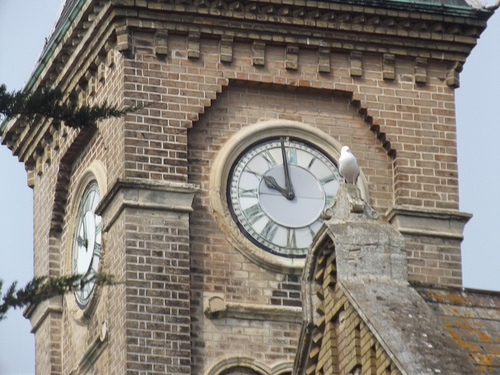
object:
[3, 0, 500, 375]
tower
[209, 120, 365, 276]
clock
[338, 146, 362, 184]
dove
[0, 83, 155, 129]
branch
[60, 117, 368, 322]
2 clocks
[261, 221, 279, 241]
numbers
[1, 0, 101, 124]
border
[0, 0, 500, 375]
sky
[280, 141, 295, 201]
hands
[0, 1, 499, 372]
scene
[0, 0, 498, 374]
building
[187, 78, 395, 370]
wall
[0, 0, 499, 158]
roof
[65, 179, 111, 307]
clock face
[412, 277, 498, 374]
roof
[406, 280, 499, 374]
old church roof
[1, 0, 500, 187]
top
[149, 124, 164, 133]
brick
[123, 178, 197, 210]
stone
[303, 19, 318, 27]
brick edgework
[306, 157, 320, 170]
roman numerals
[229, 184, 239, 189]
clock lines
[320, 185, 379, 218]
tip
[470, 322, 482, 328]
shingles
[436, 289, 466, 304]
moss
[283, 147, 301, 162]
xii